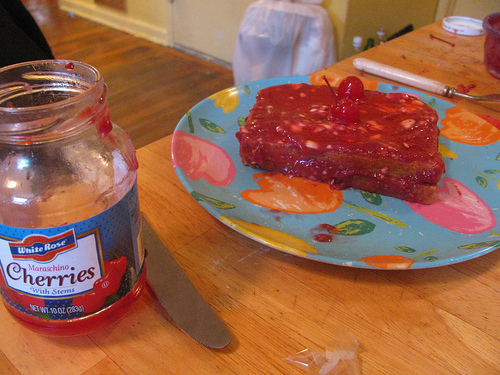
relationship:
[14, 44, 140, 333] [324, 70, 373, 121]
jar of cherries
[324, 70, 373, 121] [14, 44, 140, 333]
cherries in jar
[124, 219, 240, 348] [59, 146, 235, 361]
blade of knife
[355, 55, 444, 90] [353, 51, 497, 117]
handle of fork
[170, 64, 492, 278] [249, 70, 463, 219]
plate with food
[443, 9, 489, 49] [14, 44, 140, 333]
lid of jar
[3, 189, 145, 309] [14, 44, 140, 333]
label on jar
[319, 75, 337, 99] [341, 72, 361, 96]
stem of cherry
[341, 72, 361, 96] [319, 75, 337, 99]
cherry has stem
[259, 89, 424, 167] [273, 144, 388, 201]
bread with jam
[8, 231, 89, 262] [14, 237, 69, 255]
logo of white rose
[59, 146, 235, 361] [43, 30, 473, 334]
knife on table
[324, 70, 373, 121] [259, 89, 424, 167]
cherries on bread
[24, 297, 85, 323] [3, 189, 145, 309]
weight on label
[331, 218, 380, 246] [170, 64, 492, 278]
leaf on plate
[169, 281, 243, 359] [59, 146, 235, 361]
top of knife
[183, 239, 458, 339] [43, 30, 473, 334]
top of table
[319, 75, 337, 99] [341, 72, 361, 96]
stem on cherry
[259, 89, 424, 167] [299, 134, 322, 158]
dessert has flecks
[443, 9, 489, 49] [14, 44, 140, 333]
lid to jar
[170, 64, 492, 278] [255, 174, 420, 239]
plate has pattern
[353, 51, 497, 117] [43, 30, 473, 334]
fork on table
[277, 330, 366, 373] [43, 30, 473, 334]
cellophane on table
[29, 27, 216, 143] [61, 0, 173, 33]
floor has baseboard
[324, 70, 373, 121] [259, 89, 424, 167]
cherries on dessert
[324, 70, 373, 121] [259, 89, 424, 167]
cherries and bread